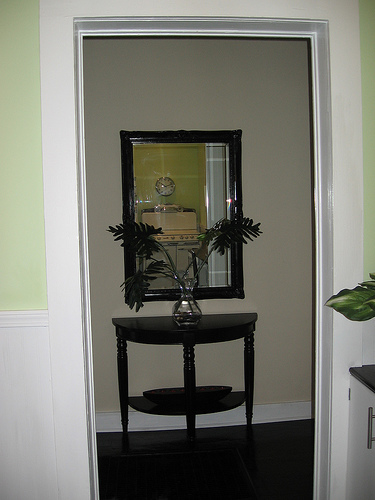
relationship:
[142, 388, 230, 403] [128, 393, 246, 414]
bowl on top of shelf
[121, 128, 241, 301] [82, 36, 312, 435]
mirror connected to wall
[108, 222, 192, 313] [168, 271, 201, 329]
plant clipping inside of vase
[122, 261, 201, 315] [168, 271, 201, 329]
plant clipping inside of vase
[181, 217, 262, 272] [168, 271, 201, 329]
plant clipping inside of vase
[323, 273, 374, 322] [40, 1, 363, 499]
leaf next to door frame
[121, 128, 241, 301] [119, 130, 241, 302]
mirror has frame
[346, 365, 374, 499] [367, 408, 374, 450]
cabinet has handle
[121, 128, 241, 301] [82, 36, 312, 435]
mirror on wall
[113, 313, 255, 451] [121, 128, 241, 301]
stand below mirror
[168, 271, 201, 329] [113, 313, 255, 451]
vase on top of stand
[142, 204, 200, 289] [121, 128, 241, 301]
reflection inside of mirror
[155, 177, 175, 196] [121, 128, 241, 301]
clock inside of mirror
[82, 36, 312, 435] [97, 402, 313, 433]
wall has baseboard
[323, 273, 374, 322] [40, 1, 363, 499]
leaf right of door frame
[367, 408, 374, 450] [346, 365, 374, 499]
handle on cabinet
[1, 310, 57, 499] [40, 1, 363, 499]
border left of door frame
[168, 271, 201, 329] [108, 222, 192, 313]
vase has plant clipping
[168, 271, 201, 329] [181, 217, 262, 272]
vase has plant clipping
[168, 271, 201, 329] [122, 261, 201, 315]
vase has plant clipping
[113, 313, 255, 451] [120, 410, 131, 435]
stand has leg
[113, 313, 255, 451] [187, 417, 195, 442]
stand has leg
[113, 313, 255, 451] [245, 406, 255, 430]
stand has leg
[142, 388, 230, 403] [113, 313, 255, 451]
bowl on top of stand